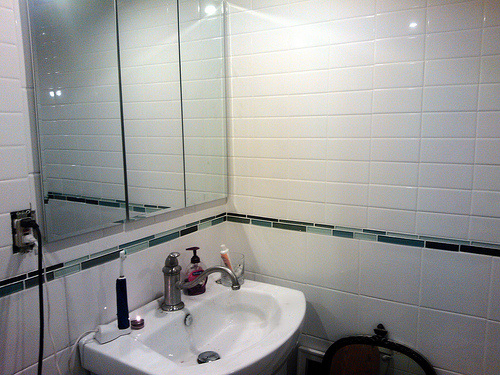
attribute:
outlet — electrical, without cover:
[12, 209, 36, 250]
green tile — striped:
[374, 230, 430, 247]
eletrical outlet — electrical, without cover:
[7, 209, 41, 249]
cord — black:
[17, 215, 51, 374]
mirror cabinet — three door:
[17, 0, 228, 243]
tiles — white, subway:
[238, 23, 494, 236]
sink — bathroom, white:
[97, 248, 327, 370]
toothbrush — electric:
[115, 247, 130, 327]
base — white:
[93, 320, 130, 344]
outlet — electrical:
[8, 206, 41, 256]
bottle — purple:
[178, 241, 210, 297]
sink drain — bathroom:
[130, 264, 277, 373]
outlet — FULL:
[14, 232, 43, 247]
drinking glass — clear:
[74, 277, 144, 354]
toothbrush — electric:
[118, 250, 128, 331]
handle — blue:
[114, 276, 129, 328]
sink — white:
[78, 267, 308, 373]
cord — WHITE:
[3, 207, 77, 366]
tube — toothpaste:
[216, 244, 236, 283]